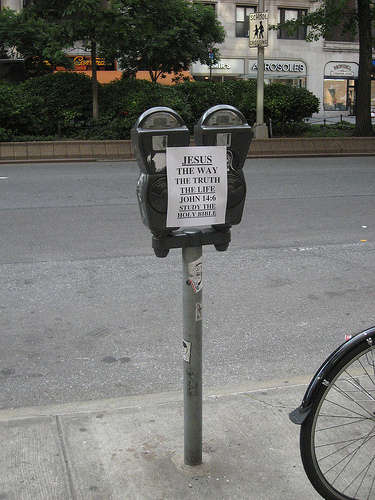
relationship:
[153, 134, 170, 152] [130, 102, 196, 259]
coin slot on left meter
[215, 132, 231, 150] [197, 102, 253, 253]
coin slot on right meter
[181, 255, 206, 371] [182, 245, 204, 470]
stickers are on pole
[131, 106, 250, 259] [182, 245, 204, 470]
meters are mounted on pole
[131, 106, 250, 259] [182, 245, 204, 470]
meter mounted on pole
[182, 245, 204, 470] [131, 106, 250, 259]
pole has meter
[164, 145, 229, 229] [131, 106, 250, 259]
sign taped to meters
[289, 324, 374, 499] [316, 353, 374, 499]
bicycle wheel has spokes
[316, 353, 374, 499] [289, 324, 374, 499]
spokes are on bicycle wheel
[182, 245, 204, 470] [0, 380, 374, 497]
pole on sidewalk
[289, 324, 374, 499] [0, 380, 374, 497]
bicycle on sidewalk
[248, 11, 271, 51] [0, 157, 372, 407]
cossing sign across street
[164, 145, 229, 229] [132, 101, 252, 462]
sign tapped to a parking meter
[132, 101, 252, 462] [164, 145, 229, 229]
parking meter has a sign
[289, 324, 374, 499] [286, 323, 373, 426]
bicycle has metal fender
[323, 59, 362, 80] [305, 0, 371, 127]
motel sign for motel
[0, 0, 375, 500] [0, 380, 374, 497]
concrete on sidewalk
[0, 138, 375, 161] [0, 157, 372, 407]
concrete barrier on side of street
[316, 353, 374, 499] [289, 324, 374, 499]
spokes are on bicycle tire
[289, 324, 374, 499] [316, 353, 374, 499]
bicycle tire has spokes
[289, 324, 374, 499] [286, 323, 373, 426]
bicycle tire has mud guard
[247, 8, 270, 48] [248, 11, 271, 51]
sign for crossing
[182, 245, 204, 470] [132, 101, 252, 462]
pole for parking meter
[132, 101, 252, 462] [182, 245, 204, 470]
parking meter has pole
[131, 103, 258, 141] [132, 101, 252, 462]
top of parking meter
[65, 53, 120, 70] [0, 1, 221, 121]
business name visible through trees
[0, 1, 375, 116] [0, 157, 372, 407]
shops are in a city street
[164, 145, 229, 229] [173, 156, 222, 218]
sign has writing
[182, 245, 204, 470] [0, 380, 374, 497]
metal pole on sidewalk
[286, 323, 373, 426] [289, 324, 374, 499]
mud guard for bike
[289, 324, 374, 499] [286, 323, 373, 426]
bike has mud guard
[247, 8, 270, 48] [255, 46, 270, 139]
sign on metal pole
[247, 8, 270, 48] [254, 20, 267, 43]
sign has drawing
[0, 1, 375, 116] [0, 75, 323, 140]
building behind bushes